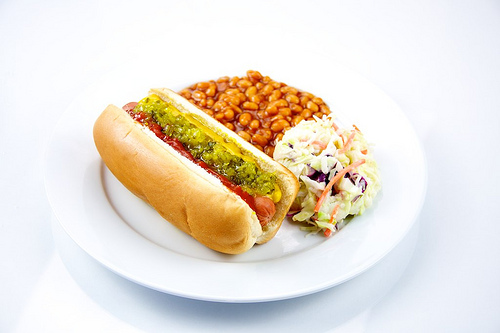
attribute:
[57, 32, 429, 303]
plate — white, ceramic, full, round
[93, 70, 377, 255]
food — junk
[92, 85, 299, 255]
hotdog — whole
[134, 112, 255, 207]
ketchup — red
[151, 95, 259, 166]
mustard — yellow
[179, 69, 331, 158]
beans — baked, brown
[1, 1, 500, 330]
background — stark white